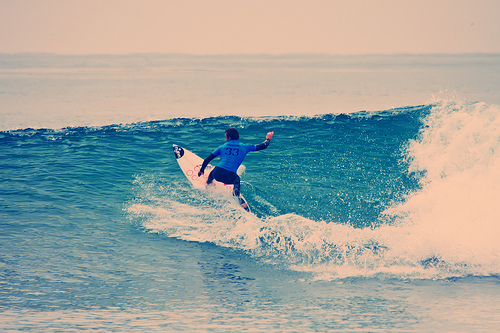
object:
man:
[196, 125, 277, 200]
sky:
[23, 7, 497, 57]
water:
[0, 51, 499, 333]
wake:
[123, 160, 457, 288]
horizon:
[3, 33, 495, 81]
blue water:
[0, 100, 499, 333]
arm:
[246, 138, 270, 150]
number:
[225, 147, 240, 156]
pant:
[206, 165, 240, 197]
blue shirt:
[198, 140, 271, 174]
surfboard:
[168, 143, 253, 215]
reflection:
[197, 217, 250, 332]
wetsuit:
[198, 127, 271, 205]